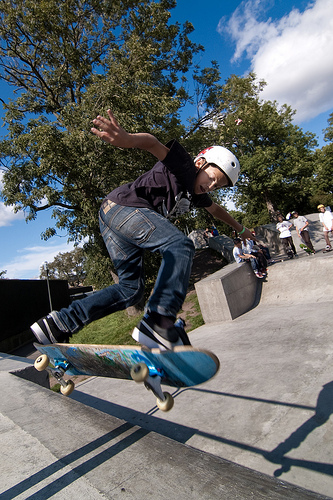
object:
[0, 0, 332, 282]
sky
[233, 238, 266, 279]
boy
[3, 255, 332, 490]
ramp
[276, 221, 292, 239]
tee shirt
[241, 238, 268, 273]
people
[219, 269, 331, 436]
concrete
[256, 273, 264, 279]
shoe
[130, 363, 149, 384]
tire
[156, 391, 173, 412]
tire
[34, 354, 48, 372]
tire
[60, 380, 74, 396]
tire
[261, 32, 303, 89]
cloud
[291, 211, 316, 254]
man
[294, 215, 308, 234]
grey shirt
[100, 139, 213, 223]
shirt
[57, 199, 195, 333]
jeans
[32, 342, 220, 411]
board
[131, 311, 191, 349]
shoe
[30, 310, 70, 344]
shoe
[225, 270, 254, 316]
wall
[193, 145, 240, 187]
helmet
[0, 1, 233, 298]
tree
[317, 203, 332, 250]
skaters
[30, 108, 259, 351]
man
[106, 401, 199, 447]
shade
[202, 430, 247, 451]
shade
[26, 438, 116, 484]
shadow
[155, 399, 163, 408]
part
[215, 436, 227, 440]
part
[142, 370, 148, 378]
part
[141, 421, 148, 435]
part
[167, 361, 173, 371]
part